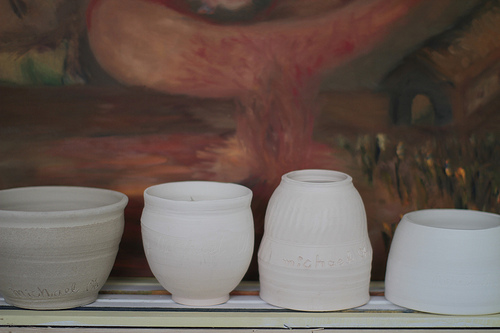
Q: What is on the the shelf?
A: Candleholders.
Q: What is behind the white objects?
A: A painting.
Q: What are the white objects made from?
A: Ceramic.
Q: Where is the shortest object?
A: The far right.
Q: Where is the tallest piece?
A: Second from the right.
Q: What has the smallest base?
A: The object second from the left.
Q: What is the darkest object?
A: The one on the far left.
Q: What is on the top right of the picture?
A: A building.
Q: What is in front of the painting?
A: Four white objects.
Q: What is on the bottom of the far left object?
A: Letters.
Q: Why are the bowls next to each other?
A: Display.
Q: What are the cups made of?
A: Ceramic.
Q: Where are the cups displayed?
A: Museum.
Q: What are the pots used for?
A: Display.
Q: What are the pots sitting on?
A: Table.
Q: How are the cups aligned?
A: Horizontal.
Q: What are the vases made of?
A: Ceramic.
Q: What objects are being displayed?
A: Pots.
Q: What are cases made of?
A: Ceramic.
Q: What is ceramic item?
A: Vase.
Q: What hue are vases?
A: White.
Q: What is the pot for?
A: Planting.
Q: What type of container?
A: Pot.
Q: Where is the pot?
A: On shelf.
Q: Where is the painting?
A: In background.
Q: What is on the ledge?
A: Bowls.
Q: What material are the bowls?
A: Ceramic.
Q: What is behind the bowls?
A: Painting.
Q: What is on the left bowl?
A: Handwriting.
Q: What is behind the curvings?
A: A painting.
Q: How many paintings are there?
A: One.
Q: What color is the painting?
A: Multicolored.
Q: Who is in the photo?
A: No one.